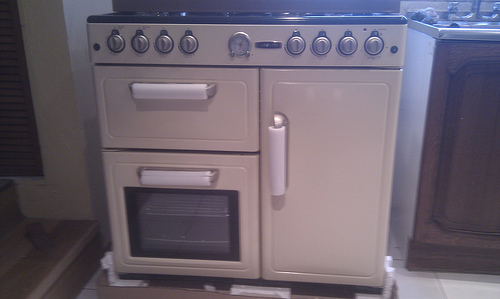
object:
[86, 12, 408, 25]
stove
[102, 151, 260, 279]
oven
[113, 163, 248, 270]
door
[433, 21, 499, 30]
sink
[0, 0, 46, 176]
shutters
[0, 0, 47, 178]
window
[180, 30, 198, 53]
knobs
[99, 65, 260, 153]
doors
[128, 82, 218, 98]
handle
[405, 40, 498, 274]
board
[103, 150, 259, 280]
cup board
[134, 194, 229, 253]
screen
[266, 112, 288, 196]
holder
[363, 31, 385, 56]
dials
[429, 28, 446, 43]
part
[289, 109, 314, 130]
part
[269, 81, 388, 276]
cabinet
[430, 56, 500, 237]
open door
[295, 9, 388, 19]
burners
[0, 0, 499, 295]
room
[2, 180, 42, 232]
another room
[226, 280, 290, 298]
foam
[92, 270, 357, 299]
box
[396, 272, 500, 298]
floor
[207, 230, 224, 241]
glass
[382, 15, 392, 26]
edge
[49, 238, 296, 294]
styrofoam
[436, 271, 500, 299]
tile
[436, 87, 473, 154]
wood stains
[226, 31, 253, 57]
temp gauge